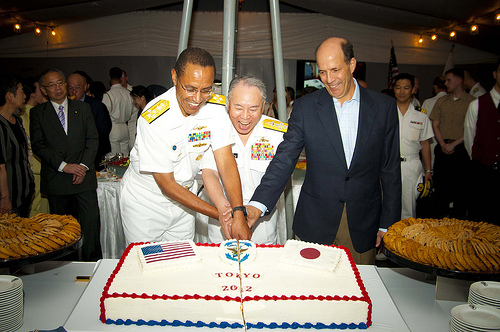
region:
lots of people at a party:
[3, 11, 483, 322]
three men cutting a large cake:
[97, 2, 398, 322]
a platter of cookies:
[378, 197, 498, 278]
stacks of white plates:
[440, 260, 495, 330]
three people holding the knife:
[121, 151, 381, 326]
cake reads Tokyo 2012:
[111, 226, 366, 327]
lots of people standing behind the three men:
[3, 48, 498, 244]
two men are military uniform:
[123, 51, 283, 231]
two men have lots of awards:
[183, 122, 270, 157]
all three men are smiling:
[158, 40, 358, 131]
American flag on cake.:
[130, 240, 200, 270]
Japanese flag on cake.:
[277, 237, 343, 271]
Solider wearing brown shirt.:
[432, 64, 469, 219]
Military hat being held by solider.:
[416, 161, 431, 201]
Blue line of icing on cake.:
[96, 317, 373, 330]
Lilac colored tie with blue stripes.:
[53, 103, 79, 133]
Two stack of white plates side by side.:
[450, 278, 498, 330]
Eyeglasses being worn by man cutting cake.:
[178, 79, 213, 98]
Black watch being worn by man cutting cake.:
[225, 190, 252, 216]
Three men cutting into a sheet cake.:
[105, 38, 407, 330]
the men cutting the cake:
[124, 25, 400, 241]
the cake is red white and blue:
[102, 227, 372, 330]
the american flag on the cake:
[128, 235, 209, 271]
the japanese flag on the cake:
[268, 227, 348, 277]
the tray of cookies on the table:
[372, 195, 496, 266]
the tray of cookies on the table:
[0, 206, 84, 263]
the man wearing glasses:
[162, 46, 230, 126]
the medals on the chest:
[187, 126, 215, 151]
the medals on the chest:
[250, 138, 274, 164]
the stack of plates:
[0, 270, 37, 330]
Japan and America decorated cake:
[96, 234, 374, 330]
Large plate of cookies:
[378, 213, 498, 285]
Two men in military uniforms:
[115, 44, 290, 246]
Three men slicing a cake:
[97, 34, 404, 330]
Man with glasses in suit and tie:
[27, 67, 105, 264]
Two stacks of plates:
[444, 276, 499, 331]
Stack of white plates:
[0, 270, 27, 330]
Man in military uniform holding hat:
[382, 70, 436, 224]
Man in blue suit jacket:
[241, 32, 403, 267]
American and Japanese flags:
[138, 236, 344, 273]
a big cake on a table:
[98, 236, 371, 330]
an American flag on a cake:
[136, 240, 198, 264]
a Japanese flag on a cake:
[280, 238, 342, 270]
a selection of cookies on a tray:
[386, 215, 499, 275]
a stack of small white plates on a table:
[448, 279, 498, 330]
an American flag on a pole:
[385, 41, 400, 89]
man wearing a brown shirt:
[430, 92, 474, 144]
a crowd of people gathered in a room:
[0, 63, 497, 260]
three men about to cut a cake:
[121, 37, 404, 239]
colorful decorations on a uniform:
[251, 140, 276, 161]